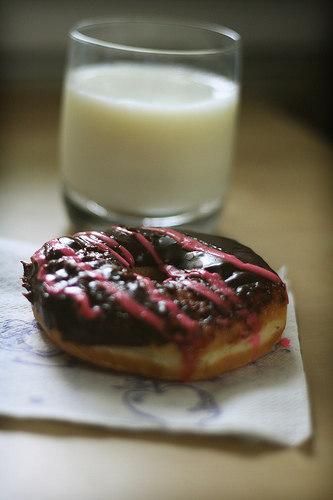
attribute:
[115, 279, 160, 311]
frosting — pink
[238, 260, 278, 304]
chocolate — glaze, glazed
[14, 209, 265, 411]
donut — chocolate, white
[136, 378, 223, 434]
apple — blue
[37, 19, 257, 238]
glass — small, short, milk, white, frosty, clear, cold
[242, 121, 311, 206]
table — wooden, wood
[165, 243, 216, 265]
icing — pink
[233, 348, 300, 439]
napkin — paper, white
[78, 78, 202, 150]
millk — white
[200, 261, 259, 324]
doughnut — glazed, chocolate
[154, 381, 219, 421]
pattern — blue